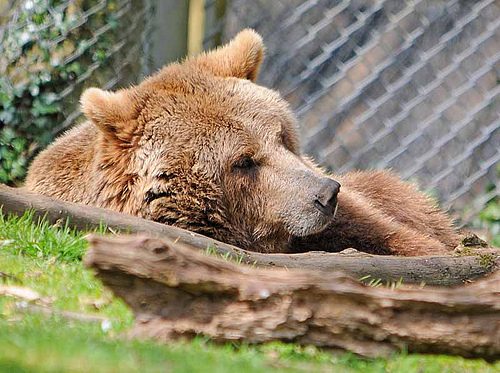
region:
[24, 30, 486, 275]
bear lying on ground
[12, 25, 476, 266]
bear is large and brown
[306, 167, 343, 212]
bears nose is black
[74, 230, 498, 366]
piece of driftwood in grass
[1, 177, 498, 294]
bear lying on wood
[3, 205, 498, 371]
pieces of wood are in the grass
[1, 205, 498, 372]
grass under the wood is green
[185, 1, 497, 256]
fence is holding in the bear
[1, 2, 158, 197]
brush is behind the fence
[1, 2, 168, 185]
bush behind the fence is green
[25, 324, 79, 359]
this is the grass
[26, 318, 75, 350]
the grass is green in color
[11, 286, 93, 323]
the area is arid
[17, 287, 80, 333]
the sand is brown in color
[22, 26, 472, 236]
this is a bear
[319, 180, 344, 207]
this is a nose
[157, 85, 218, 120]
the fur is brown in color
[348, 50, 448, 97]
this is a fence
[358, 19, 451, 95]
the fence is metallic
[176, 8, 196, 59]
this is a pole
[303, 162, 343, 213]
part of a nose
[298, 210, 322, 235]
edge of a mouth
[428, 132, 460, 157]
part of a mesh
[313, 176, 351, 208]
part of a nose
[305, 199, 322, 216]
part of a mouth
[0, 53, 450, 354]
a bear laying on the ground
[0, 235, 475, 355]
a piece of wood on the ground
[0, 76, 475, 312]
a brown bear laying on the ground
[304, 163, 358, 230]
a bear with a black nose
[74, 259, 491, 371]
a log laying on the ground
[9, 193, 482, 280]
a tree branch laying on the ground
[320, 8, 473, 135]
a chain link fence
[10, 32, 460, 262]
a large bear laying on the ground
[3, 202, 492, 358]
two pieces of wood on the ground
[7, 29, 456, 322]
a large brown bear resting on the ground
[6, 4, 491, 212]
Fence behind the bear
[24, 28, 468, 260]
The bear is brown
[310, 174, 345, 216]
The bear has a black nose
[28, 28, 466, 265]
The bear is lying down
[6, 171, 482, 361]
Logs on the ground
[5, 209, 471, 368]
Short green grass under the logs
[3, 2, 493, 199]
The fence is grey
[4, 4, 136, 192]
Green bush behind the fence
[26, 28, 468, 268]
The bear is on its side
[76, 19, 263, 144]
The bear has small round ears